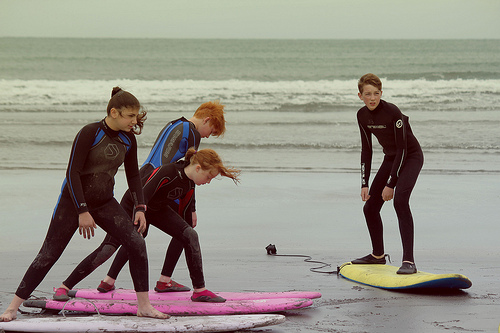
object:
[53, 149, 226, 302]
girl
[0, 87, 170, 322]
girl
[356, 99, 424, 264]
swimsuit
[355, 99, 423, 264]
wet suit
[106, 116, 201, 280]
wet suit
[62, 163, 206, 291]
wet suit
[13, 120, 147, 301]
wet suit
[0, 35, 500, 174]
ocean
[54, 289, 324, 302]
boards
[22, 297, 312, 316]
surfboard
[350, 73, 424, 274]
children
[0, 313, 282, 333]
surfboards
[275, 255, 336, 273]
ankle rope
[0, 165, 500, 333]
beach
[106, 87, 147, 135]
hair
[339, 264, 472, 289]
board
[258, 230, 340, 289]
leash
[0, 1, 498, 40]
sky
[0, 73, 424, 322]
they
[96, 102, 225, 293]
kids